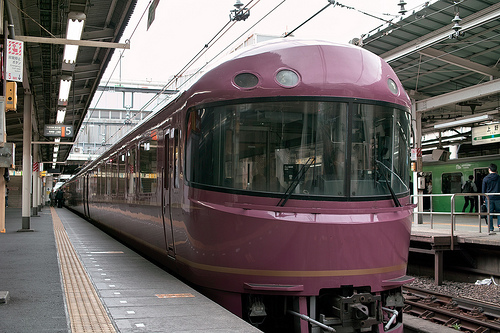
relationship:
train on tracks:
[50, 38, 422, 332] [393, 284, 500, 331]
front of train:
[176, 36, 415, 294] [50, 38, 422, 332]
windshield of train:
[180, 98, 416, 202] [50, 38, 422, 332]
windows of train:
[50, 130, 180, 215] [50, 38, 422, 332]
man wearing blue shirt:
[481, 160, 500, 232] [482, 173, 500, 193]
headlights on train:
[231, 62, 415, 104] [50, 38, 422, 332]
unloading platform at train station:
[2, 198, 268, 331] [2, 1, 499, 332]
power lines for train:
[61, 0, 408, 190] [50, 38, 422, 332]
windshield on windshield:
[180, 98, 416, 202] [180, 98, 416, 202]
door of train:
[153, 120, 182, 255] [50, 38, 422, 332]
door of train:
[80, 172, 92, 223] [50, 38, 422, 332]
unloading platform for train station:
[2, 198, 268, 331] [2, 1, 499, 332]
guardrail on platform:
[416, 189, 500, 240] [409, 208, 498, 244]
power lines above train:
[61, 0, 408, 190] [50, 38, 422, 332]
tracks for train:
[393, 284, 500, 331] [50, 38, 422, 332]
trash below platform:
[472, 271, 500, 288] [409, 208, 498, 244]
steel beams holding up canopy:
[21, 77, 47, 229] [3, 1, 140, 188]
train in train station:
[50, 38, 422, 332] [2, 1, 499, 332]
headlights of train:
[231, 62, 415, 104] [50, 38, 422, 332]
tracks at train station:
[393, 284, 500, 331] [2, 1, 499, 332]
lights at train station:
[50, 12, 88, 176] [2, 1, 499, 332]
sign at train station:
[471, 121, 500, 144] [2, 1, 499, 332]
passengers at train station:
[47, 185, 66, 208] [2, 1, 499, 332]